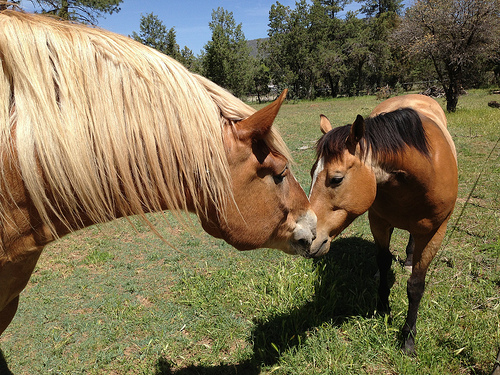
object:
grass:
[0, 85, 499, 375]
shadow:
[144, 228, 403, 375]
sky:
[10, 1, 424, 59]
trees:
[383, 0, 499, 113]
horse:
[0, 0, 320, 374]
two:
[0, 15, 466, 310]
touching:
[233, 189, 357, 265]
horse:
[295, 92, 460, 359]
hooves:
[393, 329, 419, 358]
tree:
[196, 6, 259, 102]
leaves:
[486, 33, 500, 43]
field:
[0, 86, 499, 374]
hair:
[308, 104, 429, 172]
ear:
[316, 112, 333, 134]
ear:
[350, 113, 366, 141]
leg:
[398, 220, 444, 340]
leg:
[366, 216, 397, 307]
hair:
[0, 7, 296, 260]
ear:
[236, 85, 290, 139]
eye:
[322, 174, 343, 188]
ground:
[0, 86, 499, 374]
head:
[190, 83, 318, 258]